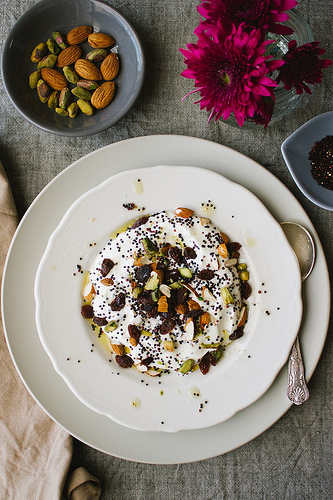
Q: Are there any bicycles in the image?
A: No, there are no bicycles.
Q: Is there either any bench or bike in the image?
A: No, there are no bikes or benches.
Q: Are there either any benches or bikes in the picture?
A: No, there are no bikes or benches.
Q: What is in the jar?
A: The flowers are in the jar.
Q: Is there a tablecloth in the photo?
A: Yes, there is a tablecloth.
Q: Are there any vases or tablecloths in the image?
A: Yes, there is a tablecloth.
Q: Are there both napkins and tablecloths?
A: Yes, there are both a tablecloth and a napkin.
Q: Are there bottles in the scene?
A: No, there are no bottles.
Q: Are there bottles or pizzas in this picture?
A: No, there are no bottles or pizzas.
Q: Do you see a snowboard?
A: No, there are no snowboards.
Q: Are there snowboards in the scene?
A: No, there are no snowboards.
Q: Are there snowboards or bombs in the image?
A: No, there are no snowboards or bombs.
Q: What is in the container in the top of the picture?
A: The flowers are in the jar.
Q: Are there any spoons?
A: Yes, there is a spoon.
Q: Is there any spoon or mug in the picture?
A: Yes, there is a spoon.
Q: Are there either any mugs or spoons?
A: Yes, there is a spoon.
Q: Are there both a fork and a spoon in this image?
A: No, there is a spoon but no forks.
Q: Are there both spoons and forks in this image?
A: No, there is a spoon but no forks.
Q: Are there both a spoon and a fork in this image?
A: No, there is a spoon but no forks.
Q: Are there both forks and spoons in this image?
A: No, there is a spoon but no forks.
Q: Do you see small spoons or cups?
A: Yes, there is a small spoon.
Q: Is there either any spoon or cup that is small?
A: Yes, the spoon is small.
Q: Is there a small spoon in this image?
A: Yes, there is a small spoon.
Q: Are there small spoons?
A: Yes, there is a small spoon.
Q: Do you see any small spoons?
A: Yes, there is a small spoon.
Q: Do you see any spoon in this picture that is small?
A: Yes, there is a spoon that is small.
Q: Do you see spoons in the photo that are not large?
A: Yes, there is a small spoon.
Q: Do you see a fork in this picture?
A: No, there are no forks.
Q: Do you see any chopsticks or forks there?
A: No, there are no forks or chopsticks.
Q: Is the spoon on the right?
A: Yes, the spoon is on the right of the image.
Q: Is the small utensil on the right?
A: Yes, the spoon is on the right of the image.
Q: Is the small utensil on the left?
A: No, the spoon is on the right of the image.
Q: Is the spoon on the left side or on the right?
A: The spoon is on the right of the image.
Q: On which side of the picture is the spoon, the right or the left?
A: The spoon is on the right of the image.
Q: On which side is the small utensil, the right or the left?
A: The spoon is on the right of the image.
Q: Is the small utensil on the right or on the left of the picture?
A: The spoon is on the right of the image.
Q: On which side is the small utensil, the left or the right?
A: The spoon is on the right of the image.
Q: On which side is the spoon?
A: The spoon is on the right of the image.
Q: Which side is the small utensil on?
A: The spoon is on the right of the image.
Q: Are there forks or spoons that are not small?
A: No, there is a spoon but it is small.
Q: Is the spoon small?
A: Yes, the spoon is small.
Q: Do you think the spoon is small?
A: Yes, the spoon is small.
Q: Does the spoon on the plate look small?
A: Yes, the spoon is small.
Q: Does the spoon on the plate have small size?
A: Yes, the spoon is small.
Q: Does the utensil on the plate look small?
A: Yes, the spoon is small.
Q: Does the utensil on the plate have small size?
A: Yes, the spoon is small.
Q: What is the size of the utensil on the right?
A: The spoon is small.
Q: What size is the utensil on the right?
A: The spoon is small.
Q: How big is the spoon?
A: The spoon is small.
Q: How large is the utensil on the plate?
A: The spoon is small.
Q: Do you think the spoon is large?
A: No, the spoon is small.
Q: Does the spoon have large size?
A: No, the spoon is small.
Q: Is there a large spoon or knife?
A: No, there is a spoon but it is small.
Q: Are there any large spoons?
A: No, there is a spoon but it is small.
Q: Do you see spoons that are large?
A: No, there is a spoon but it is small.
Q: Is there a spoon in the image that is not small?
A: No, there is a spoon but it is small.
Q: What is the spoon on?
A: The spoon is on the plate.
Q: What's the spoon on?
A: The spoon is on the plate.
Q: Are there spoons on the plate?
A: Yes, there is a spoon on the plate.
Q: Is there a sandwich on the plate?
A: No, there is a spoon on the plate.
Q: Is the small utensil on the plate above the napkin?
A: Yes, the spoon is on the plate.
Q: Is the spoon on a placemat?
A: No, the spoon is on the plate.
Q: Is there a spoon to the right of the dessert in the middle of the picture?
A: Yes, there is a spoon to the right of the dessert.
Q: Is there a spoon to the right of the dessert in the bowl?
A: Yes, there is a spoon to the right of the dessert.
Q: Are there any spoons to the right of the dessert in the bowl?
A: Yes, there is a spoon to the right of the dessert.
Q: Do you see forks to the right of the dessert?
A: No, there is a spoon to the right of the dessert.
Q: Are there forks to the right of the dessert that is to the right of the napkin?
A: No, there is a spoon to the right of the dessert.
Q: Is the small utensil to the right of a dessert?
A: Yes, the spoon is to the right of a dessert.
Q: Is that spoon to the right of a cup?
A: No, the spoon is to the right of a dessert.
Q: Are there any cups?
A: No, there are no cups.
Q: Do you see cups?
A: No, there are no cups.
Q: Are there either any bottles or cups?
A: No, there are no cups or bottles.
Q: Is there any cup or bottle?
A: No, there are no cups or bottles.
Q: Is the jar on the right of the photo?
A: Yes, the jar is on the right of the image.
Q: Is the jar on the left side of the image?
A: No, the jar is on the right of the image.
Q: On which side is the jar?
A: The jar is on the right of the image.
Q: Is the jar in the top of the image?
A: Yes, the jar is in the top of the image.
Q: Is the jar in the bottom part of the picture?
A: No, the jar is in the top of the image.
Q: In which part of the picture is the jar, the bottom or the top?
A: The jar is in the top of the image.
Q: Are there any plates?
A: Yes, there is a plate.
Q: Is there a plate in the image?
A: Yes, there is a plate.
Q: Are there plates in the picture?
A: Yes, there is a plate.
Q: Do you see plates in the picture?
A: Yes, there is a plate.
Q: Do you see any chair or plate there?
A: Yes, there is a plate.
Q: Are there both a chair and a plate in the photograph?
A: No, there is a plate but no chairs.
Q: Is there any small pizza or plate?
A: Yes, there is a small plate.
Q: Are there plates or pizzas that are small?
A: Yes, the plate is small.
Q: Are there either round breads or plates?
A: Yes, there is a round plate.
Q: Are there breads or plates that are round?
A: Yes, the plate is round.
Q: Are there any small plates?
A: Yes, there is a small plate.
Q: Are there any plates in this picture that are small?
A: Yes, there is a plate that is small.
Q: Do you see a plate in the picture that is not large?
A: Yes, there is a small plate.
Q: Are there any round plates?
A: Yes, there is a round plate.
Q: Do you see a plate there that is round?
A: Yes, there is a plate that is round.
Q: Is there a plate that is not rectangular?
A: Yes, there is a round plate.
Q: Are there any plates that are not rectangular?
A: Yes, there is a round plate.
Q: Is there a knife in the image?
A: No, there are no knives.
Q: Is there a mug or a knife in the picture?
A: No, there are no knives or mugs.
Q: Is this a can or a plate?
A: This is a plate.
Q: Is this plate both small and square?
A: No, the plate is small but round.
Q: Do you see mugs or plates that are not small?
A: No, there is a plate but it is small.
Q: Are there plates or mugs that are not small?
A: No, there is a plate but it is small.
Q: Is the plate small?
A: Yes, the plate is small.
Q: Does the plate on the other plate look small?
A: Yes, the plate is small.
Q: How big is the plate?
A: The plate is small.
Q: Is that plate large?
A: No, the plate is small.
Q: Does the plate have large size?
A: No, the plate is small.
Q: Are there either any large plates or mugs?
A: No, there is a plate but it is small.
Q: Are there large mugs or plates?
A: No, there is a plate but it is small.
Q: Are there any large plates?
A: No, there is a plate but it is small.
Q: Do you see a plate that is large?
A: No, there is a plate but it is small.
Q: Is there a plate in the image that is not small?
A: No, there is a plate but it is small.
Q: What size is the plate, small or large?
A: The plate is small.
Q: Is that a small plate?
A: Yes, that is a small plate.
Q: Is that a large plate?
A: No, that is a small plate.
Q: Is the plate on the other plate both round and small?
A: Yes, the plate is round and small.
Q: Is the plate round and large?
A: No, the plate is round but small.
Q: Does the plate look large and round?
A: No, the plate is round but small.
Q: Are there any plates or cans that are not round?
A: No, there is a plate but it is round.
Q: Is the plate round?
A: Yes, the plate is round.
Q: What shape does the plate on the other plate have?
A: The plate has round shape.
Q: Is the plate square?
A: No, the plate is round.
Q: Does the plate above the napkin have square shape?
A: No, the plate is round.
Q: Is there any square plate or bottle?
A: No, there is a plate but it is round.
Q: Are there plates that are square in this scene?
A: No, there is a plate but it is round.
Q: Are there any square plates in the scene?
A: No, there is a plate but it is round.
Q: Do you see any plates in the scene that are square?
A: No, there is a plate but it is round.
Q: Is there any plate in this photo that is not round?
A: No, there is a plate but it is round.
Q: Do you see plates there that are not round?
A: No, there is a plate but it is round.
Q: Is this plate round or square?
A: The plate is round.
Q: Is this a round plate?
A: Yes, this is a round plate.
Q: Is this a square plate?
A: No, this is a round plate.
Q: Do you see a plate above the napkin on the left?
A: Yes, there is a plate above the napkin.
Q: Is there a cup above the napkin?
A: No, there is a plate above the napkin.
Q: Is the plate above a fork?
A: No, the plate is above the napkin.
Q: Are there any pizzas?
A: No, there are no pizzas.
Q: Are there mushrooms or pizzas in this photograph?
A: No, there are no pizzas or mushrooms.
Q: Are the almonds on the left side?
A: Yes, the almonds are on the left of the image.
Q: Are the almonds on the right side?
A: No, the almonds are on the left of the image.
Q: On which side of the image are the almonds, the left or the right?
A: The almonds are on the left of the image.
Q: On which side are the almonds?
A: The almonds are on the left of the image.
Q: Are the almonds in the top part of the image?
A: Yes, the almonds are in the top of the image.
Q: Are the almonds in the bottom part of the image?
A: No, the almonds are in the top of the image.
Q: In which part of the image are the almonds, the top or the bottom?
A: The almonds are in the top of the image.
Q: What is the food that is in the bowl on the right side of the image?
A: The food is almonds.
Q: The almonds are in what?
A: The almonds are in the bowl.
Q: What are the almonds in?
A: The almonds are in the bowl.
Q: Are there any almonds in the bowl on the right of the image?
A: Yes, there are almonds in the bowl.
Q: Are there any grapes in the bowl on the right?
A: No, there are almonds in the bowl.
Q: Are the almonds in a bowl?
A: Yes, the almonds are in a bowl.